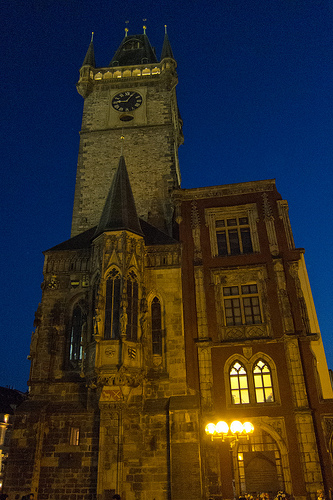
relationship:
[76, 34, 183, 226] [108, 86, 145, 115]
tower has clock